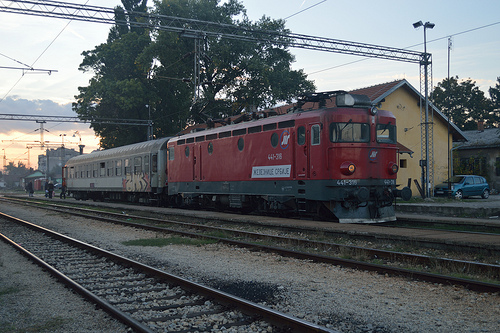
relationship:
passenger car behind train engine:
[65, 137, 166, 206] [166, 104, 397, 223]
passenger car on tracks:
[65, 137, 166, 206] [382, 218, 497, 237]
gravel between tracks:
[114, 293, 197, 306] [382, 218, 497, 237]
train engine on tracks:
[166, 104, 397, 223] [382, 218, 497, 237]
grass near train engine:
[122, 237, 216, 246] [166, 104, 397, 223]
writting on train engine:
[250, 164, 290, 176] [166, 104, 397, 223]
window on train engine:
[330, 120, 370, 143] [166, 104, 397, 223]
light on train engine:
[341, 161, 355, 174] [166, 104, 397, 223]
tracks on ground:
[382, 218, 497, 237] [1, 192, 498, 330]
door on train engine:
[293, 116, 323, 180] [166, 104, 397, 223]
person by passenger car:
[58, 182, 68, 200] [65, 137, 166, 206]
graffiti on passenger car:
[121, 172, 152, 193] [65, 137, 166, 206]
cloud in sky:
[0, 96, 96, 133] [0, 1, 499, 93]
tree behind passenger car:
[73, 1, 316, 147] [65, 137, 166, 206]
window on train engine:
[376, 123, 398, 142] [166, 104, 397, 223]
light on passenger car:
[341, 161, 355, 174] [65, 137, 166, 206]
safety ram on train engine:
[392, 185, 412, 201] [166, 104, 397, 223]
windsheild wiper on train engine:
[337, 119, 353, 132] [166, 104, 397, 223]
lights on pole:
[412, 20, 435, 30] [423, 24, 429, 198]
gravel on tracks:
[114, 293, 197, 306] [382, 218, 497, 237]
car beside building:
[433, 174, 488, 200] [362, 77, 467, 201]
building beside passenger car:
[362, 77, 467, 201] [65, 137, 166, 206]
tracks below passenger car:
[382, 218, 497, 237] [65, 137, 166, 206]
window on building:
[398, 158, 406, 170] [362, 77, 467, 201]